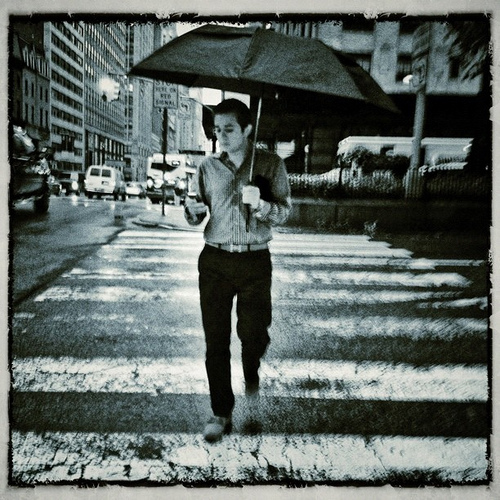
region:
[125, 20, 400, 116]
Small black open umbrella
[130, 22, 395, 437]
Man carrying an umbrella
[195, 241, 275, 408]
Man wearing black pants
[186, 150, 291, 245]
Man wearing grey shirt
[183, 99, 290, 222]
Man holding a cellphone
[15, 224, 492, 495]
White lines across the road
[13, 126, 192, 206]
Vehicles on the road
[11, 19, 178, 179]
Tall building in the streer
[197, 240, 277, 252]
White belt on man's wast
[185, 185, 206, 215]
Cellphone in man's hand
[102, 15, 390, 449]
man with umbrella in street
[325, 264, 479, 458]
white lines painted on road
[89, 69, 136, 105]
traffic light in the street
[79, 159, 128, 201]
van in the street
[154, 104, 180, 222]
street sign on sidewalk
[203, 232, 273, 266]
belt on a man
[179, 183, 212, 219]
phone in man's hand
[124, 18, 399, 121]
umbrella in man's hand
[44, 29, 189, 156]
buildings along side of street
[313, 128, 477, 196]
truck in the street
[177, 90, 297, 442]
A pefson walking across a street.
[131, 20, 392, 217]
an umbrella in a person's hadn.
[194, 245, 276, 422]
a pair of black pants on a man.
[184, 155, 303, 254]
a shirt on a person walking across a street.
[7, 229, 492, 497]
a rain soaked street.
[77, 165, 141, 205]
a van in front of a tall building.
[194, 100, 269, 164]
a person wearing a hat.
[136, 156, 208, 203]
a van parked on a street.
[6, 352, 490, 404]
a large white line.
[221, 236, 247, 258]
a belt buckle.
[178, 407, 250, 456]
right shoe on a man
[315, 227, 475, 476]
white painted lines on the street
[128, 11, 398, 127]
umbrella man is holding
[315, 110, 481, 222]
white truck in the street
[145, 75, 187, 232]
street sign on a pole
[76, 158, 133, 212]
white van in the street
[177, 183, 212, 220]
cell phone in man's hand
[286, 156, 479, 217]
black fence near sidewalk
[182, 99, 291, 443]
a man looking at his phone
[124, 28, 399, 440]
a man carrying a umbrella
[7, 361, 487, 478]
white strips on the road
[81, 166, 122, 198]
a back of a van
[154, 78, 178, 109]
a black and white sign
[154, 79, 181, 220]
a black and white sign on a pole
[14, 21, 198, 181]
a row of buildings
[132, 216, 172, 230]
the curb of the road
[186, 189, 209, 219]
a cell phone in right hand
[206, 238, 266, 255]
a white belt in pants